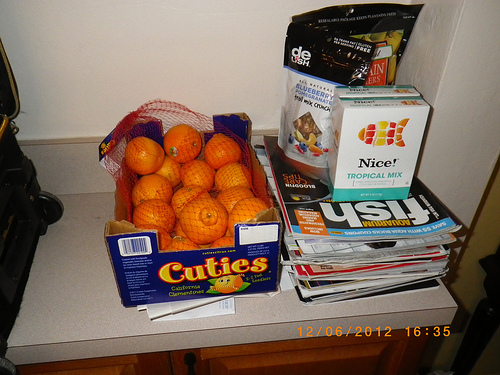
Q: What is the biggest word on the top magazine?
A: Fish.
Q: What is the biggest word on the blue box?
A: Cuties.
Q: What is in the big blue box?
A: Clementines.